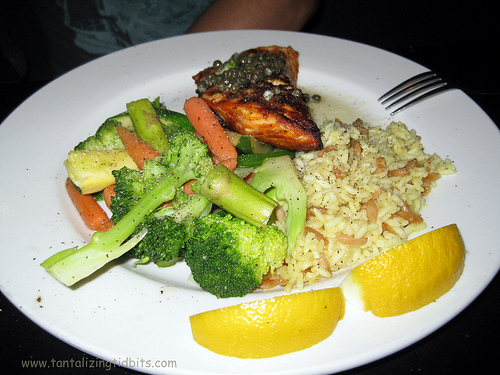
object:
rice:
[256, 118, 457, 293]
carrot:
[65, 177, 111, 231]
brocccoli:
[75, 111, 137, 150]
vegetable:
[39, 132, 306, 298]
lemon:
[188, 287, 346, 359]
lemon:
[339, 224, 465, 319]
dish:
[0, 28, 500, 374]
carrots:
[117, 125, 163, 171]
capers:
[196, 51, 283, 95]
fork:
[377, 71, 456, 116]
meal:
[41, 44, 465, 361]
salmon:
[191, 45, 323, 151]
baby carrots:
[184, 96, 238, 170]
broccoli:
[183, 213, 287, 297]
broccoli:
[39, 130, 215, 286]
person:
[57, 0, 213, 57]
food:
[38, 46, 464, 360]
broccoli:
[249, 148, 307, 255]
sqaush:
[63, 151, 139, 194]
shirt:
[62, 0, 212, 56]